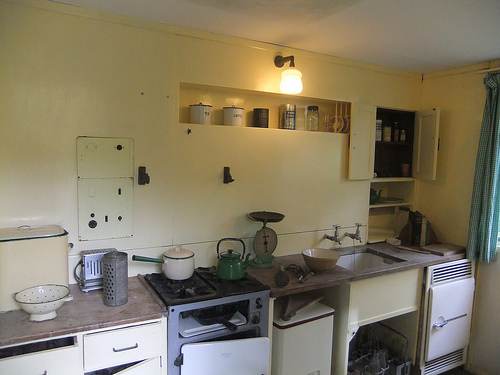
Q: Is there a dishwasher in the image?
A: Yes, there is a dishwasher.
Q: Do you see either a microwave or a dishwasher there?
A: Yes, there is a dishwasher.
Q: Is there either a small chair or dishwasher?
A: Yes, there is a small dishwasher.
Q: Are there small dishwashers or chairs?
A: Yes, there is a small dishwasher.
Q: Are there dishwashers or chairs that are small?
A: Yes, the dishwasher is small.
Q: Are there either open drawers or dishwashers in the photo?
A: Yes, there is an open dishwasher.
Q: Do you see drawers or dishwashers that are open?
A: Yes, the dishwasher is open.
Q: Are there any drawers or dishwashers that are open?
A: Yes, the dishwasher is open.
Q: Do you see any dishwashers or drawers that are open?
A: Yes, the dishwasher is open.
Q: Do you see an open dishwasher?
A: Yes, there is an open dishwasher.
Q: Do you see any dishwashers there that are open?
A: Yes, there is a dishwasher that is open.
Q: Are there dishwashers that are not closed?
A: Yes, there is a open dishwasher.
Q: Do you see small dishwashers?
A: Yes, there is a small dishwasher.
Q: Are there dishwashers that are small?
A: Yes, there is a dishwasher that is small.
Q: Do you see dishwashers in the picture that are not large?
A: Yes, there is a small dishwasher.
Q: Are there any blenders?
A: No, there are no blenders.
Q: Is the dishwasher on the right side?
A: Yes, the dishwasher is on the right of the image.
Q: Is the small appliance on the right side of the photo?
A: Yes, the dishwasher is on the right of the image.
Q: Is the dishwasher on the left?
A: No, the dishwasher is on the right of the image.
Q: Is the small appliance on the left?
A: No, the dishwasher is on the right of the image.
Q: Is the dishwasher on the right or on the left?
A: The dishwasher is on the right of the image.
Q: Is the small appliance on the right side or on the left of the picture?
A: The dishwasher is on the right of the image.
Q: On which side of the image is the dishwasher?
A: The dishwasher is on the right of the image.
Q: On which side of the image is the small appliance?
A: The dishwasher is on the right of the image.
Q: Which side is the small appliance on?
A: The dishwasher is on the right of the image.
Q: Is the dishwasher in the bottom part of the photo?
A: Yes, the dishwasher is in the bottom of the image.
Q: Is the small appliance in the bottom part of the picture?
A: Yes, the dishwasher is in the bottom of the image.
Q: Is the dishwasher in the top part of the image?
A: No, the dishwasher is in the bottom of the image.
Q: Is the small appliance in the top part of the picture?
A: No, the dishwasher is in the bottom of the image.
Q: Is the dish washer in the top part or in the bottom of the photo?
A: The dish washer is in the bottom of the image.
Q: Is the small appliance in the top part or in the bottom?
A: The dish washer is in the bottom of the image.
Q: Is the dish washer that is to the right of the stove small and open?
A: Yes, the dishwasher is small and open.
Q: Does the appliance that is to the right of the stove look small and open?
A: Yes, the dishwasher is small and open.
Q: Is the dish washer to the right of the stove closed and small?
A: No, the dish washer is small but open.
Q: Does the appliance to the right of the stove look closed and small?
A: No, the dish washer is small but open.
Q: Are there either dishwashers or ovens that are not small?
A: No, there is a dishwasher but it is small.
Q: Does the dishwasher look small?
A: Yes, the dishwasher is small.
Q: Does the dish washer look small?
A: Yes, the dish washer is small.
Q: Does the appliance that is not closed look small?
A: Yes, the dish washer is small.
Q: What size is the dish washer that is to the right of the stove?
A: The dishwasher is small.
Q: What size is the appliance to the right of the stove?
A: The dishwasher is small.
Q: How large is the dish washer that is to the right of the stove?
A: The dishwasher is small.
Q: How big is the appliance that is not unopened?
A: The dishwasher is small.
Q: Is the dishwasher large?
A: No, the dishwasher is small.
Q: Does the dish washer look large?
A: No, the dish washer is small.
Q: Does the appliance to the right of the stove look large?
A: No, the dish washer is small.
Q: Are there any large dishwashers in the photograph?
A: No, there is a dishwasher but it is small.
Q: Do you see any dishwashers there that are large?
A: No, there is a dishwasher but it is small.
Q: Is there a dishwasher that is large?
A: No, there is a dishwasher but it is small.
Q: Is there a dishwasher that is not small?
A: No, there is a dishwasher but it is small.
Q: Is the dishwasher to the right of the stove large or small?
A: The dishwasher is small.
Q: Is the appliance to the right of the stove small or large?
A: The dishwasher is small.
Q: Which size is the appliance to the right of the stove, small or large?
A: The dishwasher is small.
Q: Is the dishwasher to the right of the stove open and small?
A: Yes, the dishwasher is open and small.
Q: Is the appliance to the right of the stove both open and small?
A: Yes, the dishwasher is open and small.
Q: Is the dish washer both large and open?
A: No, the dish washer is open but small.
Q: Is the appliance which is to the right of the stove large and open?
A: No, the dish washer is open but small.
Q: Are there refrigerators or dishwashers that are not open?
A: No, there is a dishwasher but it is open.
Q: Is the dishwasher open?
A: Yes, the dishwasher is open.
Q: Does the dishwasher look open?
A: Yes, the dishwasher is open.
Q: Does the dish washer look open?
A: Yes, the dish washer is open.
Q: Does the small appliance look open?
A: Yes, the dish washer is open.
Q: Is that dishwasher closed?
A: No, the dishwasher is open.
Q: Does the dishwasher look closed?
A: No, the dishwasher is open.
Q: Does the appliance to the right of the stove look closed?
A: No, the dishwasher is open.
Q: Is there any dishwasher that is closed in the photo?
A: No, there is a dishwasher but it is open.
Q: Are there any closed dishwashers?
A: No, there is a dishwasher but it is open.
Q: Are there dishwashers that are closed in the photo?
A: No, there is a dishwasher but it is open.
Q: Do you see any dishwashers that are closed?
A: No, there is a dishwasher but it is open.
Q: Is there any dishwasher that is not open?
A: No, there is a dishwasher but it is open.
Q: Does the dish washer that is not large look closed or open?
A: The dishwasher is open.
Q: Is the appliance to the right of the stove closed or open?
A: The dishwasher is open.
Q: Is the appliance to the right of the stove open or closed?
A: The dishwasher is open.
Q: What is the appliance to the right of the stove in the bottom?
A: The appliance is a dishwasher.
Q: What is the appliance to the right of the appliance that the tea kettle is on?
A: The appliance is a dishwasher.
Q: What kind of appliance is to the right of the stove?
A: The appliance is a dishwasher.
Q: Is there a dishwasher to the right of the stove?
A: Yes, there is a dishwasher to the right of the stove.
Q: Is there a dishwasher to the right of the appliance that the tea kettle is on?
A: Yes, there is a dishwasher to the right of the stove.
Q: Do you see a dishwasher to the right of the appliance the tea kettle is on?
A: Yes, there is a dishwasher to the right of the stove.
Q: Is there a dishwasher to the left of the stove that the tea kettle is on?
A: No, the dishwasher is to the right of the stove.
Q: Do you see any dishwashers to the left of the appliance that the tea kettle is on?
A: No, the dishwasher is to the right of the stove.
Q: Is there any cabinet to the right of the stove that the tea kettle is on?
A: No, there is a dishwasher to the right of the stove.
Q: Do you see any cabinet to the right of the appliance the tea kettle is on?
A: No, there is a dishwasher to the right of the stove.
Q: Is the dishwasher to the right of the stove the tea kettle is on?
A: Yes, the dishwasher is to the right of the stove.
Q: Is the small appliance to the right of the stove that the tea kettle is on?
A: Yes, the dishwasher is to the right of the stove.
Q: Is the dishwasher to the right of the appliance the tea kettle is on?
A: Yes, the dishwasher is to the right of the stove.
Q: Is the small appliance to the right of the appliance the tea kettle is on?
A: Yes, the dishwasher is to the right of the stove.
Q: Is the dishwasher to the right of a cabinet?
A: No, the dishwasher is to the right of the stove.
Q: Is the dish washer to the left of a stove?
A: No, the dish washer is to the right of a stove.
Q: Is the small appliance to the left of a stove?
A: No, the dish washer is to the right of a stove.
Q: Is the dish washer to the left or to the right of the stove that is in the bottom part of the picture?
A: The dish washer is to the right of the stove.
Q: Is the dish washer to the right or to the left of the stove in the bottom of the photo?
A: The dish washer is to the right of the stove.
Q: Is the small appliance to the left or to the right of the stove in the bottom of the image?
A: The dish washer is to the right of the stove.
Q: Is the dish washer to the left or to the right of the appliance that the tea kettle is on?
A: The dish washer is to the right of the stove.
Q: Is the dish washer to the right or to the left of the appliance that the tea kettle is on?
A: The dish washer is to the right of the stove.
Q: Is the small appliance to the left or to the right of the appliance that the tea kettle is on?
A: The dish washer is to the right of the stove.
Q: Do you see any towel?
A: No, there are no towels.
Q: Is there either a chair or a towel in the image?
A: No, there are no towels or chairs.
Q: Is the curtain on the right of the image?
A: Yes, the curtain is on the right of the image.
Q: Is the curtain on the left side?
A: No, the curtain is on the right of the image.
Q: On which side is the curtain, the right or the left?
A: The curtain is on the right of the image.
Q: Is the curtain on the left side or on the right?
A: The curtain is on the right of the image.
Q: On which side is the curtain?
A: The curtain is on the right of the image.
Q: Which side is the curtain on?
A: The curtain is on the right of the image.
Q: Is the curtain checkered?
A: Yes, the curtain is checkered.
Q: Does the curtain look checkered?
A: Yes, the curtain is checkered.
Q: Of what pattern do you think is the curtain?
A: The curtain is checkered.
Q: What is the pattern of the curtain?
A: The curtain is checkered.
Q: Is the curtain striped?
A: No, the curtain is checkered.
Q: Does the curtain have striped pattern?
A: No, the curtain is checkered.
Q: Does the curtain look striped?
A: No, the curtain is checkered.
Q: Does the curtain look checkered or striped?
A: The curtain is checkered.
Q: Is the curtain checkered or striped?
A: The curtain is checkered.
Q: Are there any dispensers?
A: No, there are no dispensers.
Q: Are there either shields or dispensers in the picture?
A: No, there are no dispensers or shields.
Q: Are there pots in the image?
A: Yes, there is a pot.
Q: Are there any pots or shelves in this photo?
A: Yes, there is a pot.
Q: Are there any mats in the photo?
A: No, there are no mats.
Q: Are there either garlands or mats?
A: No, there are no mats or garlands.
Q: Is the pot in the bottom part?
A: Yes, the pot is in the bottom of the image.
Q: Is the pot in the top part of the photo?
A: No, the pot is in the bottom of the image.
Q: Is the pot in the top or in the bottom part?
A: The pot is in the bottom of the image.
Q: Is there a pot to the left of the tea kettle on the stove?
A: Yes, there is a pot to the left of the tea kettle.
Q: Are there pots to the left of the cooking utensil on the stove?
A: Yes, there is a pot to the left of the tea kettle.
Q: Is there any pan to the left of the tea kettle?
A: No, there is a pot to the left of the tea kettle.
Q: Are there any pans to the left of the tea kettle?
A: No, there is a pot to the left of the tea kettle.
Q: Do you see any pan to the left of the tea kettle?
A: No, there is a pot to the left of the tea kettle.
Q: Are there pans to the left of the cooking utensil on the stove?
A: No, there is a pot to the left of the tea kettle.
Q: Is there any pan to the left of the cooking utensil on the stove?
A: No, there is a pot to the left of the tea kettle.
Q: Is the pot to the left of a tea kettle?
A: Yes, the pot is to the left of a tea kettle.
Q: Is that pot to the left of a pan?
A: No, the pot is to the left of a tea kettle.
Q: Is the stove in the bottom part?
A: Yes, the stove is in the bottom of the image.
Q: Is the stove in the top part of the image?
A: No, the stove is in the bottom of the image.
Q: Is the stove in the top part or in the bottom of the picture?
A: The stove is in the bottom of the image.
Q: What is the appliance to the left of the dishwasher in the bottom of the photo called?
A: The appliance is a stove.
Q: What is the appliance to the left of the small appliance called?
A: The appliance is a stove.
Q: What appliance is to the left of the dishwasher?
A: The appliance is a stove.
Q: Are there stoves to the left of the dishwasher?
A: Yes, there is a stove to the left of the dishwasher.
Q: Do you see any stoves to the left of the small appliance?
A: Yes, there is a stove to the left of the dishwasher.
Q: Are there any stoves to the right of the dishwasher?
A: No, the stove is to the left of the dishwasher.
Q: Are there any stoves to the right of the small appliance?
A: No, the stove is to the left of the dishwasher.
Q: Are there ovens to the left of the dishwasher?
A: No, there is a stove to the left of the dishwasher.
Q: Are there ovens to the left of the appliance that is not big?
A: No, there is a stove to the left of the dishwasher.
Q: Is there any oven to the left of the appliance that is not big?
A: No, there is a stove to the left of the dishwasher.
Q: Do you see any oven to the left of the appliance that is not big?
A: No, there is a stove to the left of the dishwasher.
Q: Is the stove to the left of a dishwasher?
A: Yes, the stove is to the left of a dishwasher.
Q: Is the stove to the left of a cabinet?
A: No, the stove is to the left of a dishwasher.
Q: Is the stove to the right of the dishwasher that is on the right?
A: No, the stove is to the left of the dishwasher.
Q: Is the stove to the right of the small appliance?
A: No, the stove is to the left of the dishwasher.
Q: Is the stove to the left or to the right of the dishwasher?
A: The stove is to the left of the dishwasher.